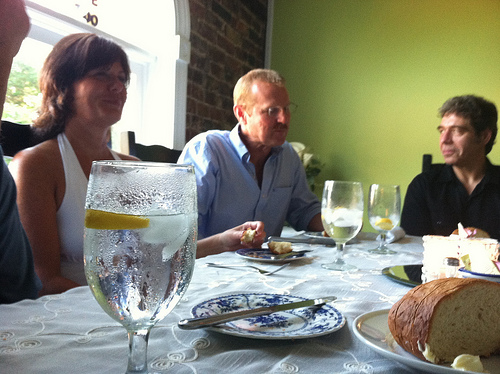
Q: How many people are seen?
A: 4.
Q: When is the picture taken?
A: Daytime.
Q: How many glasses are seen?
A: 3.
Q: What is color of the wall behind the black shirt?
A: Green.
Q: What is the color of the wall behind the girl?
A: Red.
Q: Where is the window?
A: In the wall.